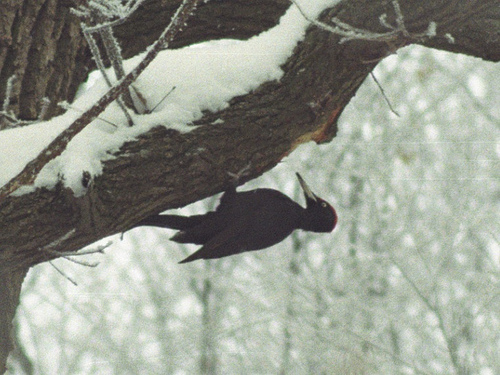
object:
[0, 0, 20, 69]
bark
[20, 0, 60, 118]
bark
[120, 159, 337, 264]
bird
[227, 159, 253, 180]
claw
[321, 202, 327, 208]
eye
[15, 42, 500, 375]
ground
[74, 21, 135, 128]
branch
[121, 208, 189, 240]
tail feathers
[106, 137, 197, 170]
bark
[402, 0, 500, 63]
bark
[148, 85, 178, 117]
twigs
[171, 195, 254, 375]
trees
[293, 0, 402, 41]
branch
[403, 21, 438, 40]
branch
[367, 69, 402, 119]
branch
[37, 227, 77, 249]
branch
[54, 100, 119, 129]
branch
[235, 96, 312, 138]
bark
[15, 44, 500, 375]
snow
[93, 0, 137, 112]
branch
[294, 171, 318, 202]
beak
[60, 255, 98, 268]
branch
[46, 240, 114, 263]
branch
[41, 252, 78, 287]
branch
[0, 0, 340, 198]
snow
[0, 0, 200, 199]
branch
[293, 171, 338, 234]
head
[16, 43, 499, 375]
background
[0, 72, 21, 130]
branch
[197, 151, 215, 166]
crevasses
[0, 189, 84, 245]
tree bark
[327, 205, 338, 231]
patch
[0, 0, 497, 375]
tree